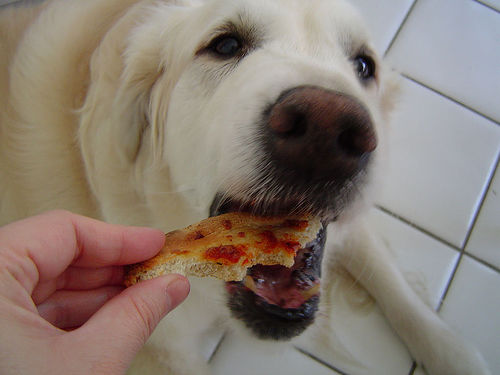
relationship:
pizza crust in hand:
[173, 205, 347, 280] [6, 204, 188, 374]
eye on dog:
[352, 45, 399, 81] [2, 3, 495, 366]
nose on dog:
[277, 87, 375, 179] [2, 3, 495, 366]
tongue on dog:
[244, 265, 316, 316] [2, 3, 495, 366]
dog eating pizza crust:
[2, 3, 495, 366] [125, 205, 323, 288]